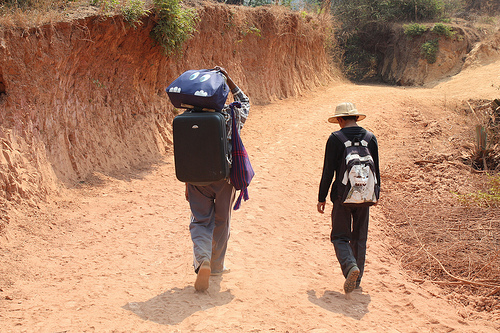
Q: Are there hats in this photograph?
A: Yes, there is a hat.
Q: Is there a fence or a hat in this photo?
A: Yes, there is a hat.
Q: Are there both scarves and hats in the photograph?
A: No, there is a hat but no scarves.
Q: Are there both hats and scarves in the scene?
A: No, there is a hat but no scarves.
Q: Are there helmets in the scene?
A: No, there are no helmets.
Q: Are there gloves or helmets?
A: No, there are no helmets or gloves.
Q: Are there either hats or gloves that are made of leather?
A: No, there is a hat but it is made of straw.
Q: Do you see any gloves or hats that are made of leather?
A: No, there is a hat but it is made of straw.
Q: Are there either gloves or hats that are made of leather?
A: No, there is a hat but it is made of straw.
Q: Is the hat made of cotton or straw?
A: The hat is made of straw.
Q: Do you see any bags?
A: Yes, there is a bag.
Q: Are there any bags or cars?
A: Yes, there is a bag.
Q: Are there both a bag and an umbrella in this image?
A: No, there is a bag but no umbrellas.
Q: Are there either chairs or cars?
A: No, there are no chairs or cars.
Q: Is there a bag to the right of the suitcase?
A: Yes, there is a bag to the right of the suitcase.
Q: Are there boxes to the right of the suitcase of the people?
A: No, there is a bag to the right of the suitcase.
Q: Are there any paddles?
A: No, there are no paddles.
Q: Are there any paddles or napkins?
A: No, there are no paddles or napkins.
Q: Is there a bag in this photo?
A: Yes, there is a bag.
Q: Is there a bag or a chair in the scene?
A: Yes, there is a bag.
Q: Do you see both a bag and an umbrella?
A: No, there is a bag but no umbrellas.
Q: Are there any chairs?
A: No, there are no chairs.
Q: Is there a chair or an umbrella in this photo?
A: No, there are no chairs or umbrellas.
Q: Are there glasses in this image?
A: No, there are no glasses.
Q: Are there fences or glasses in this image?
A: No, there are no glasses or fences.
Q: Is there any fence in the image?
A: No, there are no fences.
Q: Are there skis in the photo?
A: No, there are no skis.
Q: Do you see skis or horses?
A: No, there are no skis or horses.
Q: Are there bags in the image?
A: Yes, there is a bag.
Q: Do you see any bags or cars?
A: Yes, there is a bag.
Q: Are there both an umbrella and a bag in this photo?
A: No, there is a bag but no umbrellas.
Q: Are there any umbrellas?
A: No, there are no umbrellas.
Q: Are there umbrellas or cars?
A: No, there are no umbrellas or cars.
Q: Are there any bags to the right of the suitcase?
A: Yes, there is a bag to the right of the suitcase.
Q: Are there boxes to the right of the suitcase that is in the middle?
A: No, there is a bag to the right of the suitcase.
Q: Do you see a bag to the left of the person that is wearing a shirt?
A: Yes, there is a bag to the left of the person.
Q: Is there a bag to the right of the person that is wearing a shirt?
A: No, the bag is to the left of the person.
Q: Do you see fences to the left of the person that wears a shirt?
A: No, there is a bag to the left of the person.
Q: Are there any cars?
A: No, there are no cars.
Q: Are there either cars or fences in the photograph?
A: No, there are no cars or fences.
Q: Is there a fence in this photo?
A: No, there are no fences.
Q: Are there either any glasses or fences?
A: No, there are no fences or glasses.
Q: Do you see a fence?
A: No, there are no fences.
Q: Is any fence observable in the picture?
A: No, there are no fences.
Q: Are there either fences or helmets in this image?
A: No, there are no fences or helmets.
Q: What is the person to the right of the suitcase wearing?
A: The person is wearing a shirt.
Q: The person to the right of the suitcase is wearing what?
A: The person is wearing a shirt.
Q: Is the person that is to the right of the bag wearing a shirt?
A: Yes, the person is wearing a shirt.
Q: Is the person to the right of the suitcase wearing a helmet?
A: No, the person is wearing a shirt.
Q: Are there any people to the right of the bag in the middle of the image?
A: Yes, there is a person to the right of the bag.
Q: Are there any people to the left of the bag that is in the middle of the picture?
A: No, the person is to the right of the bag.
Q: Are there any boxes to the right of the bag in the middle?
A: No, there is a person to the right of the bag.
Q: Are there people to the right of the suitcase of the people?
A: Yes, there is a person to the right of the suitcase.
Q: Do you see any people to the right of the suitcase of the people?
A: Yes, there is a person to the right of the suitcase.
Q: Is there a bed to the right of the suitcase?
A: No, there is a person to the right of the suitcase.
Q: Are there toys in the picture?
A: No, there are no toys.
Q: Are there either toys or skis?
A: No, there are no toys or skis.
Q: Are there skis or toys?
A: No, there are no toys or skis.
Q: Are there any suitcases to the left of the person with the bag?
A: Yes, there is a suitcase to the left of the person.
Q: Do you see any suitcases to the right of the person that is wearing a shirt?
A: No, the suitcase is to the left of the person.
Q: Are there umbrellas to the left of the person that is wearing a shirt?
A: No, there is a suitcase to the left of the person.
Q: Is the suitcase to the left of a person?
A: Yes, the suitcase is to the left of a person.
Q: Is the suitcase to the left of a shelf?
A: No, the suitcase is to the left of a person.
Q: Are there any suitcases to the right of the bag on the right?
A: No, the suitcase is to the left of the bag.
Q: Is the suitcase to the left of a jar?
A: No, the suitcase is to the left of the bag.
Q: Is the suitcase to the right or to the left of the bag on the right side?
A: The suitcase is to the left of the bag.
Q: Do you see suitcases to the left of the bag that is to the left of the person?
A: Yes, there is a suitcase to the left of the bag.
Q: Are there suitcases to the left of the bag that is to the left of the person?
A: Yes, there is a suitcase to the left of the bag.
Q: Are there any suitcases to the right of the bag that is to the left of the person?
A: No, the suitcase is to the left of the bag.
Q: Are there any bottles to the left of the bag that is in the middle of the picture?
A: No, there is a suitcase to the left of the bag.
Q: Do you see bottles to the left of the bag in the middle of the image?
A: No, there is a suitcase to the left of the bag.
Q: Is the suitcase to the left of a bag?
A: Yes, the suitcase is to the left of a bag.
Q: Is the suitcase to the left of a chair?
A: No, the suitcase is to the left of a bag.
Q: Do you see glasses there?
A: No, there are no glasses.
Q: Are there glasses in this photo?
A: No, there are no glasses.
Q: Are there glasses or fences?
A: No, there are no glasses or fences.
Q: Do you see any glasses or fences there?
A: No, there are no glasses or fences.